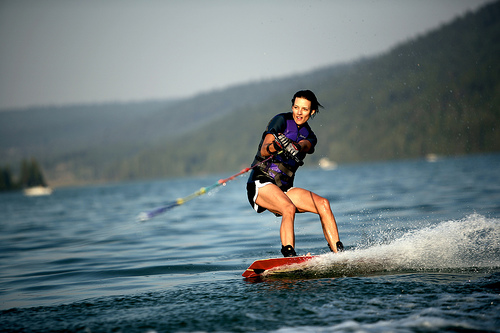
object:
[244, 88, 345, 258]
woman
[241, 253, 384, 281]
ski board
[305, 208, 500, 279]
water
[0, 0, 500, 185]
air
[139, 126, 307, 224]
tether rope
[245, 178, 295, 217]
shorts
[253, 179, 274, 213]
white trim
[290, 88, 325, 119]
hair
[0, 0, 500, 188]
tall hill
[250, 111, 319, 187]
purple lifevest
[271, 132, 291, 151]
gloves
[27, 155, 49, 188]
trees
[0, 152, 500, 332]
sea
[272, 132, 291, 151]
hands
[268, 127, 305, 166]
tight grip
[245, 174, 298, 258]
muscular legs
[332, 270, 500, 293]
wave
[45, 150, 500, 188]
horizon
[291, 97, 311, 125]
woman's face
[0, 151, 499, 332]
river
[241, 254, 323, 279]
red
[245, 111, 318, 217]
suit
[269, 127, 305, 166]
large handle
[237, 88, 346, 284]
backwards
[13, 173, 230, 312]
blue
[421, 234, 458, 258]
white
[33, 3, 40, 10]
clouds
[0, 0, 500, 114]
sky